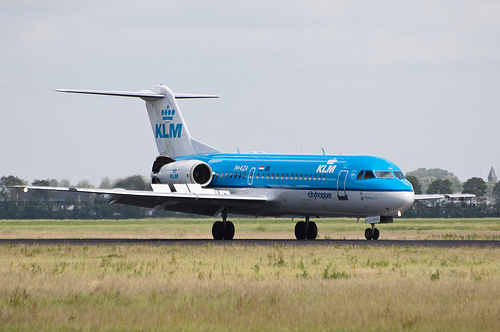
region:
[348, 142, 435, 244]
front of a plane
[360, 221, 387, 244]
wheel of a plane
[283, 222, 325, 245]
wheel of a plane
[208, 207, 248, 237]
wheel of a plane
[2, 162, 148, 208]
wing of a plane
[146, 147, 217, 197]
engine of a plane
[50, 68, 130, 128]
wing of a plane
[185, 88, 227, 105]
wing of a plane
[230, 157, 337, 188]
window of a plane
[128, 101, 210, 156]
tail of a plane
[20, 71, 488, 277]
a blue and white plane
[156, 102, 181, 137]
a blue crown on plane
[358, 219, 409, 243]
a front tire of plane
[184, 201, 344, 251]
two rear tires of plane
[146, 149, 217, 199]
one jet engine of plane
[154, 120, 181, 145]
blue KLM on plane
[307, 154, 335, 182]
white KLM on plane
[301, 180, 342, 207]
dark blue letters on side of plane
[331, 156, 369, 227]
a door near front of plane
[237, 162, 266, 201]
a door over the wing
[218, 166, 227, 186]
side window on plane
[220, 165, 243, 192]
side window on plane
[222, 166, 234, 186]
side window on plane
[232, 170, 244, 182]
side window on plane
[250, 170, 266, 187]
side window on plane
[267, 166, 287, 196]
side window on plane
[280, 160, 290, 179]
side window on plane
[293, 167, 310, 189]
side window on plane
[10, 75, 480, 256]
Plane on the ground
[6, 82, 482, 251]
Plane is on the ground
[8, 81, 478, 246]
Airplane on the ground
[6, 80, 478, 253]
Airplane is on the ground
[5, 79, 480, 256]
Blue and white plane on the ground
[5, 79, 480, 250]
Blue and white plane is on the ground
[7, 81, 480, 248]
Blue and white airplane on the ground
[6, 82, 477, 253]
Blue and white airplane is on the ground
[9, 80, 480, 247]
Plane on the runway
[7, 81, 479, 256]
Airplane on the runway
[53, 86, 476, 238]
Blue and white plane on runway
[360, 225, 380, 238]
Front landing gear on plane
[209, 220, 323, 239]
Rear landing gear on plane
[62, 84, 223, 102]
White tail fins on plane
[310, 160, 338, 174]
White letters on side of plane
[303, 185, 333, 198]
Blue letters on side of plane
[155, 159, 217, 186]
White engine cover on plane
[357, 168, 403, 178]
Cockpit windows on plane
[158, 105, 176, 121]
Blue logo on tail of plane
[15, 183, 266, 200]
White wing on plane